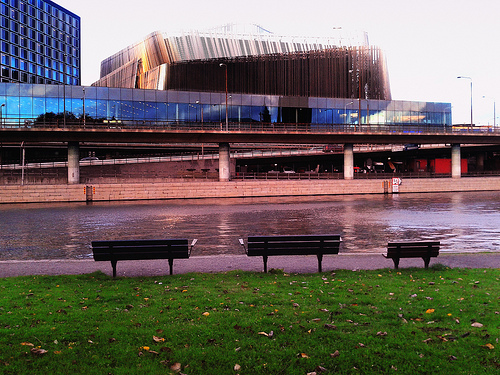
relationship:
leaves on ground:
[137, 304, 233, 359] [108, 291, 377, 359]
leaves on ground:
[389, 299, 468, 370] [120, 286, 393, 358]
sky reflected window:
[1, 0, 498, 135] [389, 108, 404, 126]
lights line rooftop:
[446, 56, 485, 127] [58, 63, 455, 103]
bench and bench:
[91, 238, 197, 279] [380, 230, 450, 270]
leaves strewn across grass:
[308, 299, 399, 336] [1, 264, 499, 374]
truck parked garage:
[405, 139, 464, 175] [24, 123, 484, 213]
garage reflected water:
[3, 121, 499, 203] [6, 182, 499, 276]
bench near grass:
[236, 229, 343, 275] [228, 275, 367, 320]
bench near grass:
[91, 238, 197, 279] [1, 264, 499, 374]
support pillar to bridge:
[66, 137, 81, 184] [3, 115, 499, 182]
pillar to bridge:
[339, 151, 363, 180] [8, 117, 496, 187]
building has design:
[93, 27, 413, 187] [105, 22, 421, 133]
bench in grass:
[86, 226, 197, 273] [291, 302, 396, 345]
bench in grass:
[238, 233, 344, 273] [291, 302, 396, 345]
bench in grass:
[383, 240, 443, 262] [291, 302, 396, 345]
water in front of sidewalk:
[0, 190, 498, 261] [1, 251, 499, 279]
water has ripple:
[0, 190, 498, 261] [417, 231, 455, 238]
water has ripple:
[0, 190, 498, 261] [448, 235, 484, 240]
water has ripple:
[0, 190, 498, 261] [340, 244, 363, 249]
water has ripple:
[0, 190, 498, 261] [340, 233, 360, 241]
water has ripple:
[0, 190, 498, 261] [194, 240, 235, 247]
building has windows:
[0, 0, 87, 87] [14, 12, 64, 53]